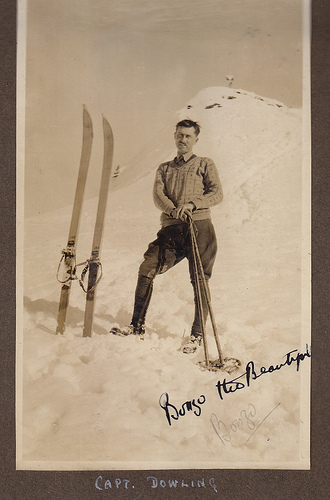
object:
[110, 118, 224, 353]
man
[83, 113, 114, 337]
ski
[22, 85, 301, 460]
snow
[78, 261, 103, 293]
belted loops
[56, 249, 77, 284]
belted loops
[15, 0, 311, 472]
photo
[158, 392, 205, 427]
signature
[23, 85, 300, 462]
hill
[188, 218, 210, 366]
pole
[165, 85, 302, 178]
mountain top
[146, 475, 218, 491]
writing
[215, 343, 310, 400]
writing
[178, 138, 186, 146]
mustache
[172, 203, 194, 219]
hand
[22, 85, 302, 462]
ground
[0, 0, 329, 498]
photograph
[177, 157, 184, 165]
tie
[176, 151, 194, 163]
shirt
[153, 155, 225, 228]
sweater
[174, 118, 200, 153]
head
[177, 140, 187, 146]
mouth